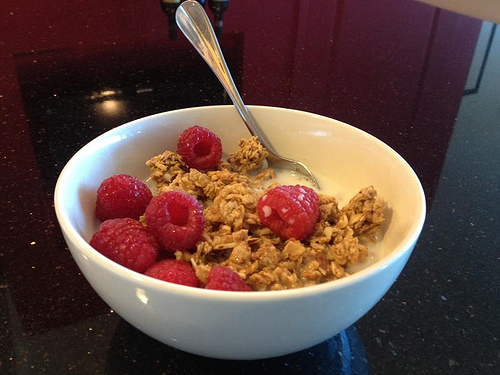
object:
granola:
[145, 135, 386, 289]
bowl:
[53, 104, 431, 360]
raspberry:
[257, 184, 321, 239]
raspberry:
[177, 125, 223, 169]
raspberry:
[145, 190, 204, 250]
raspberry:
[95, 175, 153, 220]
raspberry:
[89, 216, 160, 273]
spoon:
[175, 0, 320, 192]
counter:
[1, 2, 499, 374]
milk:
[133, 158, 393, 281]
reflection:
[302, 326, 381, 375]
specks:
[114, 43, 115, 44]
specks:
[54, 94, 57, 96]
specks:
[32, 50, 34, 52]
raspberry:
[205, 266, 253, 292]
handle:
[173, 0, 278, 156]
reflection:
[87, 82, 127, 119]